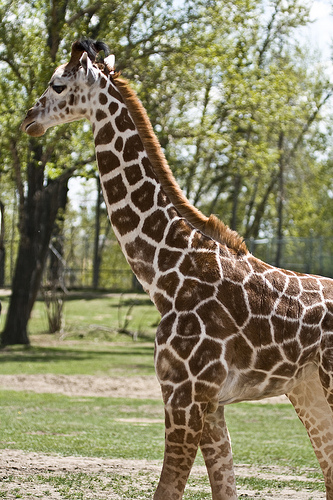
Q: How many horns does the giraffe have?
A: 2.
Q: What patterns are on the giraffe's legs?
A: Spots.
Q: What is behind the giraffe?
A: Tree.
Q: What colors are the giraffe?
A: Brown and white.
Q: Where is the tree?
A: Behind the giraffe.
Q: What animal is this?
A: Giraffe.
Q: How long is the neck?
A: Very long.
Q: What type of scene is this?
A: Outdoor.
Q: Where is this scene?
A: Park.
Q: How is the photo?
A: Clear.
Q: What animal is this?
A: Giraffe.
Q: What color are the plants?
A: Green.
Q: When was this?
A: Daytime.